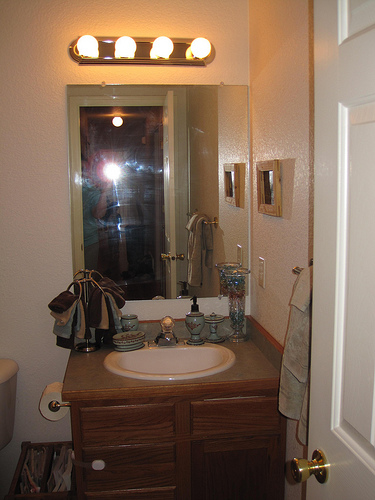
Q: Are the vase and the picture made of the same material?
A: No, the vase is made of glass and the picture is made of wood.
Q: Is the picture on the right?
A: Yes, the picture is on the right of the image.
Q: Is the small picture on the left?
A: No, the picture is on the right of the image.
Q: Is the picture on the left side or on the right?
A: The picture is on the right of the image.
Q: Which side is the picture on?
A: The picture is on the right of the image.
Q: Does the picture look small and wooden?
A: Yes, the picture is small and wooden.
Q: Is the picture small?
A: Yes, the picture is small.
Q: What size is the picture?
A: The picture is small.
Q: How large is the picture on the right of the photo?
A: The picture is small.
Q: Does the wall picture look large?
A: No, the picture is small.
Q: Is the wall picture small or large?
A: The picture is small.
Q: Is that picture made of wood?
A: Yes, the picture is made of wood.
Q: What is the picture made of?
A: The picture is made of wood.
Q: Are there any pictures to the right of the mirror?
A: Yes, there is a picture to the right of the mirror.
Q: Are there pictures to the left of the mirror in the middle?
A: No, the picture is to the right of the mirror.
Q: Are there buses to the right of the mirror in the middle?
A: No, there is a picture to the right of the mirror.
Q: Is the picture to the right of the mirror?
A: Yes, the picture is to the right of the mirror.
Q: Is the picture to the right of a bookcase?
A: No, the picture is to the right of the mirror.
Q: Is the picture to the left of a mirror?
A: No, the picture is to the right of a mirror.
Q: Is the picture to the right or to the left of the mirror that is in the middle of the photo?
A: The picture is to the right of the mirror.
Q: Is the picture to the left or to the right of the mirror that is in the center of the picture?
A: The picture is to the right of the mirror.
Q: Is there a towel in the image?
A: Yes, there is a towel.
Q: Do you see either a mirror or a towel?
A: Yes, there is a towel.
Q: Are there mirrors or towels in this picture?
A: Yes, there is a towel.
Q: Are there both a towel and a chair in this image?
A: No, there is a towel but no chairs.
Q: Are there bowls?
A: No, there are no bowls.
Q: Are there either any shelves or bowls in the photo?
A: No, there are no bowls or shelves.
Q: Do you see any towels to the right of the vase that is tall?
A: Yes, there is a towel to the right of the vase.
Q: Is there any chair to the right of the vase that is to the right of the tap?
A: No, there is a towel to the right of the vase.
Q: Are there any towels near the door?
A: Yes, there is a towel near the door.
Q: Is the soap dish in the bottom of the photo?
A: Yes, the soap dish is in the bottom of the image.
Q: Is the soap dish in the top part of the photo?
A: No, the soap dish is in the bottom of the image.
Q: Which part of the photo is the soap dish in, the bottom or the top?
A: The soap dish is in the bottom of the image.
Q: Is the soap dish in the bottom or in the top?
A: The soap dish is in the bottom of the image.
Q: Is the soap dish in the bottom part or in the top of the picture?
A: The soap dish is in the bottom of the image.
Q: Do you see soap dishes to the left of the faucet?
A: Yes, there is a soap dish to the left of the faucet.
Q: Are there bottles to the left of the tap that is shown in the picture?
A: No, there is a soap dish to the left of the tap.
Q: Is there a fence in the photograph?
A: No, there are no fences.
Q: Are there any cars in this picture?
A: No, there are no cars.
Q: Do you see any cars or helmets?
A: No, there are no cars or helmets.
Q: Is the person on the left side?
A: Yes, the person is on the left of the image.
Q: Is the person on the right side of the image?
A: No, the person is on the left of the image.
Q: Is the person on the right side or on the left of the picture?
A: The person is on the left of the image.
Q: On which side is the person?
A: The person is on the left of the image.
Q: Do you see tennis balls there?
A: No, there are no tennis balls.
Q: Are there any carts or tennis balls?
A: No, there are no tennis balls or carts.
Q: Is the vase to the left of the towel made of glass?
A: Yes, the vase is made of glass.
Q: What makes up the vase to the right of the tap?
A: The vase is made of glass.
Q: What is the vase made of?
A: The vase is made of glass.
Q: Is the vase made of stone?
A: No, the vase is made of glass.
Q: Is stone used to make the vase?
A: No, the vase is made of glass.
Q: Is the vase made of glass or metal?
A: The vase is made of glass.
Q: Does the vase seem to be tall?
A: Yes, the vase is tall.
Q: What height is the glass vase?
A: The vase is tall.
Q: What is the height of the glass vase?
A: The vase is tall.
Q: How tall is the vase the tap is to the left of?
A: The vase is tall.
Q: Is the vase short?
A: No, the vase is tall.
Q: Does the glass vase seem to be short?
A: No, the vase is tall.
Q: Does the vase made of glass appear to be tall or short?
A: The vase is tall.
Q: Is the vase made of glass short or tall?
A: The vase is tall.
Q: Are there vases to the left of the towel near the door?
A: Yes, there is a vase to the left of the towel.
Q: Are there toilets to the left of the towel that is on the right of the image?
A: No, there is a vase to the left of the towel.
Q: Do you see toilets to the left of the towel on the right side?
A: No, there is a vase to the left of the towel.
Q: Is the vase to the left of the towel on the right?
A: Yes, the vase is to the left of the towel.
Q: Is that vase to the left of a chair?
A: No, the vase is to the left of the towel.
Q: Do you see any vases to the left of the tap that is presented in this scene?
A: No, the vase is to the right of the tap.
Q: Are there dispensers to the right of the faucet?
A: No, there is a vase to the right of the faucet.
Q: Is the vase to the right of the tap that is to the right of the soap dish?
A: Yes, the vase is to the right of the tap.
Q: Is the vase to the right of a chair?
A: No, the vase is to the right of the tap.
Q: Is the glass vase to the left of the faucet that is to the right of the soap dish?
A: No, the vase is to the right of the faucet.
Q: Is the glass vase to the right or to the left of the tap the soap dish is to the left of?
A: The vase is to the right of the faucet.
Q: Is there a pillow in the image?
A: No, there are no pillows.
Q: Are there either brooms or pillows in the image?
A: No, there are no pillows or brooms.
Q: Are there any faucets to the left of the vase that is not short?
A: Yes, there is a faucet to the left of the vase.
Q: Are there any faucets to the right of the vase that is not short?
A: No, the faucet is to the left of the vase.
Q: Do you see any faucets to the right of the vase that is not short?
A: No, the faucet is to the left of the vase.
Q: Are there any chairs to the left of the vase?
A: No, there is a faucet to the left of the vase.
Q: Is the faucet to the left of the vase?
A: Yes, the faucet is to the left of the vase.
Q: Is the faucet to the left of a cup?
A: No, the faucet is to the left of the vase.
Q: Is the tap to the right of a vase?
A: No, the tap is to the left of a vase.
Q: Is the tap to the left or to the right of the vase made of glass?
A: The tap is to the left of the vase.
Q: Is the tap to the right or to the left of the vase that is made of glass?
A: The tap is to the left of the vase.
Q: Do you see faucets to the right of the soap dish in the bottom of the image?
A: Yes, there is a faucet to the right of the soap dish.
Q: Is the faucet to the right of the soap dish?
A: Yes, the faucet is to the right of the soap dish.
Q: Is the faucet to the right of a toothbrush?
A: No, the faucet is to the right of the soap dish.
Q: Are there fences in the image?
A: No, there are no fences.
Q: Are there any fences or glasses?
A: No, there are no fences or glasses.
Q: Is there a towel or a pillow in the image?
A: Yes, there is a towel.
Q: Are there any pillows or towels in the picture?
A: Yes, there is a towel.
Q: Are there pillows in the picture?
A: No, there are no pillows.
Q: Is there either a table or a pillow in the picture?
A: No, there are no pillows or tables.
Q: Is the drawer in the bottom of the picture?
A: Yes, the drawer is in the bottom of the image.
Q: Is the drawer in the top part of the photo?
A: No, the drawer is in the bottom of the image.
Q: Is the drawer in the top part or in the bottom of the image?
A: The drawer is in the bottom of the image.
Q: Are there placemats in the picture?
A: No, there are no placemats.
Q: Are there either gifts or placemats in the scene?
A: No, there are no placemats or gifts.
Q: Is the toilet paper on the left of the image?
A: Yes, the toilet paper is on the left of the image.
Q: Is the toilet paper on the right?
A: No, the toilet paper is on the left of the image.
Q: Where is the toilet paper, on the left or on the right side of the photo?
A: The toilet paper is on the left of the image.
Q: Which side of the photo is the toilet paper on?
A: The toilet paper is on the left of the image.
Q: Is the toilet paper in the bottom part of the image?
A: Yes, the toilet paper is in the bottom of the image.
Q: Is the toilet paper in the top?
A: No, the toilet paper is in the bottom of the image.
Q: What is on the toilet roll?
A: The toilet paper is on the toilet roll.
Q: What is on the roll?
A: The toilet paper is on the toilet roll.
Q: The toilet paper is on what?
A: The toilet paper is on the roll.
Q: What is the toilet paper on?
A: The toilet paper is on the roll.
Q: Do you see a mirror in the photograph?
A: Yes, there is a mirror.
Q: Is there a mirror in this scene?
A: Yes, there is a mirror.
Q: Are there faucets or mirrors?
A: Yes, there is a mirror.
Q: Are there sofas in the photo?
A: No, there are no sofas.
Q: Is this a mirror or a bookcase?
A: This is a mirror.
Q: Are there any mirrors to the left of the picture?
A: Yes, there is a mirror to the left of the picture.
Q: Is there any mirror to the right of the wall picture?
A: No, the mirror is to the left of the picture.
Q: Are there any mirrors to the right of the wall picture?
A: No, the mirror is to the left of the picture.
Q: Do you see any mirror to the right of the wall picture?
A: No, the mirror is to the left of the picture.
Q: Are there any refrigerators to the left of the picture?
A: No, there is a mirror to the left of the picture.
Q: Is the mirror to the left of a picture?
A: Yes, the mirror is to the left of a picture.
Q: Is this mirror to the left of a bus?
A: No, the mirror is to the left of a picture.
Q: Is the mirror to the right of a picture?
A: No, the mirror is to the left of a picture.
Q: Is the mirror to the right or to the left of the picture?
A: The mirror is to the left of the picture.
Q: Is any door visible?
A: Yes, there is a door.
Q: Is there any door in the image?
A: Yes, there is a door.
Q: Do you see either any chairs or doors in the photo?
A: Yes, there is a door.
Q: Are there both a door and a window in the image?
A: No, there is a door but no windows.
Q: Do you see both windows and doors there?
A: No, there is a door but no windows.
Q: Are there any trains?
A: No, there are no trains.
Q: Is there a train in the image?
A: No, there are no trains.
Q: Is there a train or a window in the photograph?
A: No, there are no trains or windows.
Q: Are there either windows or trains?
A: No, there are no trains or windows.